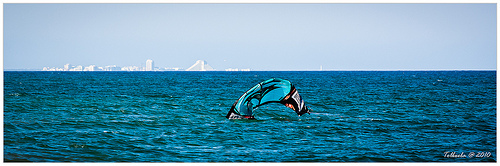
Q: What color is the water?
A: Blue.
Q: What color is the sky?
A: Light blue.